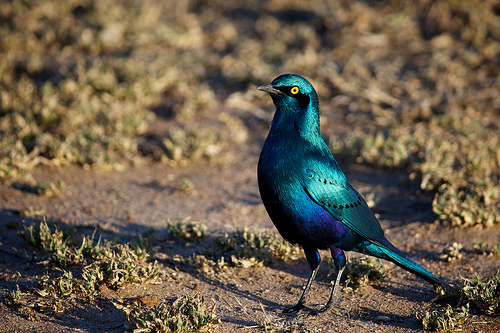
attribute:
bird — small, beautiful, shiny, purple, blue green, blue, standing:
[253, 72, 441, 318]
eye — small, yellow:
[291, 86, 301, 94]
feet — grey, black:
[275, 264, 344, 319]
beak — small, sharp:
[258, 83, 279, 94]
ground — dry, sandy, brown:
[0, 1, 499, 333]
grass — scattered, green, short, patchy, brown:
[1, 1, 499, 333]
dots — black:
[307, 173, 362, 211]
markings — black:
[275, 83, 311, 109]